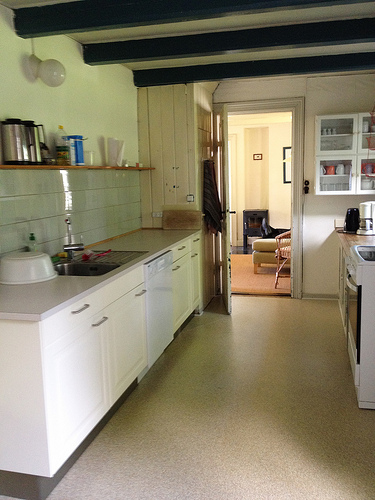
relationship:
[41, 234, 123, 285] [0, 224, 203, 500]
sink on cabinetry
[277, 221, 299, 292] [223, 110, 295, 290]
chair in living room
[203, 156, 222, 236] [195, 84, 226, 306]
towel on wall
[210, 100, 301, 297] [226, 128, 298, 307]
door in living room